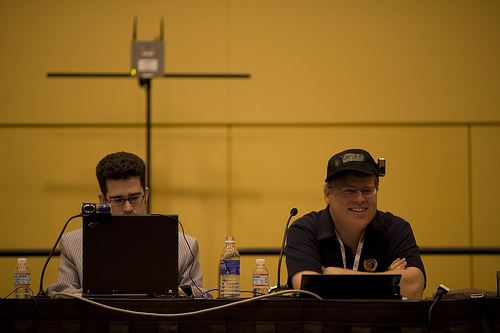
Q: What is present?
A: People.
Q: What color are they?
A: White.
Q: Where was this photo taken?
A: At a desk.